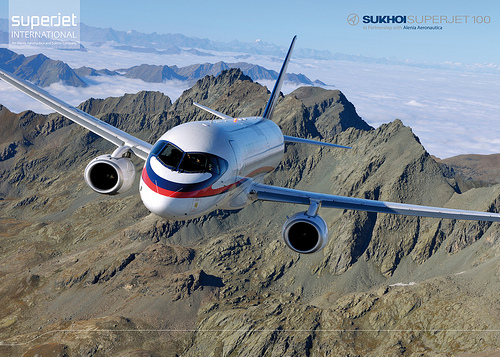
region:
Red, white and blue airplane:
[3, 31, 498, 256]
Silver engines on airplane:
[79, 139, 331, 271]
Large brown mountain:
[1, 64, 496, 355]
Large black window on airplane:
[149, 132, 235, 184]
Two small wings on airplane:
[182, 81, 352, 163]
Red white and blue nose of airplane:
[138, 159, 221, 227]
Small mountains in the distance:
[0, 0, 499, 96]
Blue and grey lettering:
[341, 8, 498, 36]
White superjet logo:
[6, 1, 84, 51]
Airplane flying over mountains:
[3, 23, 498, 258]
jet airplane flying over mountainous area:
[2, 33, 497, 252]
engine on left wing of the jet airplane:
[281, 208, 329, 253]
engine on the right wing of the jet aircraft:
[84, 153, 136, 193]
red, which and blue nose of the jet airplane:
[137, 172, 223, 219]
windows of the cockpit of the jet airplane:
[154, 136, 221, 180]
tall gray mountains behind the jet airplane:
[8, 67, 483, 342]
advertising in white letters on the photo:
[0, 3, 82, 50]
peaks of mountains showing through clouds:
[1, 22, 334, 87]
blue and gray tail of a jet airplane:
[192, 35, 349, 155]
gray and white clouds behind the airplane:
[364, 64, 496, 116]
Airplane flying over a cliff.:
[0, 34, 499, 253]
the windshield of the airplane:
[157, 147, 207, 174]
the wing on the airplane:
[364, 198, 486, 230]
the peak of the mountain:
[199, 65, 246, 90]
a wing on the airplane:
[3, 66, 92, 127]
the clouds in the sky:
[86, 72, 146, 93]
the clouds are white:
[380, 73, 461, 118]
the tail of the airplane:
[277, 33, 301, 90]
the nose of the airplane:
[135, 198, 172, 215]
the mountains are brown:
[142, 60, 197, 79]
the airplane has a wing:
[363, 196, 478, 224]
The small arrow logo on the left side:
[345, 13, 357, 28]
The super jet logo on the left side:
[7, 10, 79, 50]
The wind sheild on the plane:
[160, 146, 215, 173]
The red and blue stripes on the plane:
[142, 159, 274, 196]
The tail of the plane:
[186, 35, 353, 158]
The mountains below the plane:
[0, 100, 490, 354]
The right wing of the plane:
[246, 176, 496, 246]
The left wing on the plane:
[3, 63, 138, 197]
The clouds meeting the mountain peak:
[365, 64, 487, 143]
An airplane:
[3, 45, 494, 236]